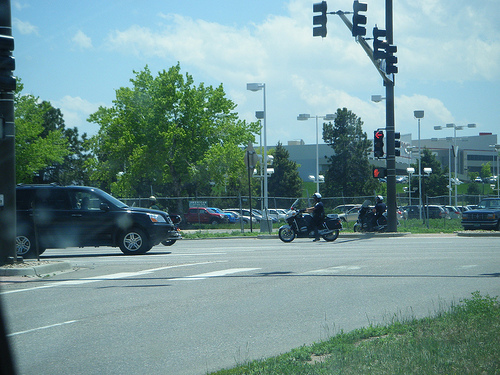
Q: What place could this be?
A: It is a road.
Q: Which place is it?
A: It is a road.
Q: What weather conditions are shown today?
A: It is clear.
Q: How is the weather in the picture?
A: It is clear.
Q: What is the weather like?
A: It is clear.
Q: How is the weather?
A: It is clear.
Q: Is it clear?
A: Yes, it is clear.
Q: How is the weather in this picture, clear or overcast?
A: It is clear.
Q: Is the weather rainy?
A: No, it is clear.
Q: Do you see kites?
A: No, there are no kites.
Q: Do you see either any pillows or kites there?
A: No, there are no kites or pillows.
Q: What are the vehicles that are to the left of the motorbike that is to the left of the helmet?
A: The vehicles are cars.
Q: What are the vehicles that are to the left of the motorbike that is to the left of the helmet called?
A: The vehicles are cars.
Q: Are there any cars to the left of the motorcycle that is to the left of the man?
A: Yes, there are cars to the left of the motorbike.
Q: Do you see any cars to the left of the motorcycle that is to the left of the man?
A: Yes, there are cars to the left of the motorbike.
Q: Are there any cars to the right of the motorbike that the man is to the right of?
A: No, the cars are to the left of the motorbike.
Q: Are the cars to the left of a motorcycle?
A: Yes, the cars are to the left of a motorcycle.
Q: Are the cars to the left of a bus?
A: No, the cars are to the left of a motorcycle.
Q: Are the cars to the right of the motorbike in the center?
A: No, the cars are to the left of the motorbike.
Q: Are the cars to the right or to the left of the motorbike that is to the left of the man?
A: The cars are to the left of the motorbike.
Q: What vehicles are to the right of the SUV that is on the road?
A: The vehicles are cars.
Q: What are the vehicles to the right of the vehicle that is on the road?
A: The vehicles are cars.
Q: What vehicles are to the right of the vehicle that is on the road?
A: The vehicles are cars.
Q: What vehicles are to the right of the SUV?
A: The vehicles are cars.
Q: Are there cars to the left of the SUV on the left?
A: No, the cars are to the right of the SUV.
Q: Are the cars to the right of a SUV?
A: Yes, the cars are to the right of a SUV.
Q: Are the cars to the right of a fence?
A: No, the cars are to the right of a SUV.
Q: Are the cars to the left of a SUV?
A: No, the cars are to the right of a SUV.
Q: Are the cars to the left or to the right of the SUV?
A: The cars are to the right of the SUV.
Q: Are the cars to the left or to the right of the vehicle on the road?
A: The cars are to the right of the SUV.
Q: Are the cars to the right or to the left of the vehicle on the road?
A: The cars are to the right of the SUV.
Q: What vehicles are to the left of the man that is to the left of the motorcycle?
A: The vehicles are cars.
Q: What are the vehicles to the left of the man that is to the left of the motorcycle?
A: The vehicles are cars.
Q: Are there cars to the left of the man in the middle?
A: Yes, there are cars to the left of the man.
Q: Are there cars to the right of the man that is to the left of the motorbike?
A: No, the cars are to the left of the man.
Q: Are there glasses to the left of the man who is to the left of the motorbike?
A: No, there are cars to the left of the man.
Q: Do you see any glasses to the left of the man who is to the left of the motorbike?
A: No, there are cars to the left of the man.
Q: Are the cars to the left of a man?
A: Yes, the cars are to the left of a man.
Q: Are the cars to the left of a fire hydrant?
A: No, the cars are to the left of a man.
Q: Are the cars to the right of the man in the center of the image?
A: No, the cars are to the left of the man.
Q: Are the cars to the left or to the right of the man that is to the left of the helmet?
A: The cars are to the left of the man.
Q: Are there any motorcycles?
A: Yes, there is a motorcycle.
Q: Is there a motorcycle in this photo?
A: Yes, there is a motorcycle.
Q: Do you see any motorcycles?
A: Yes, there is a motorcycle.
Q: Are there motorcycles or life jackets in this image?
A: Yes, there is a motorcycle.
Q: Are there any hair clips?
A: No, there are no hair clips.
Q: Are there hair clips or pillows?
A: No, there are no hair clips or pillows.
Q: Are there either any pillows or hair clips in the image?
A: No, there are no hair clips or pillows.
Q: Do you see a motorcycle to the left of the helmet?
A: Yes, there is a motorcycle to the left of the helmet.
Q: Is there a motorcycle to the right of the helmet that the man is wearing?
A: No, the motorcycle is to the left of the helmet.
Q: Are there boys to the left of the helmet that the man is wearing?
A: No, there is a motorcycle to the left of the helmet.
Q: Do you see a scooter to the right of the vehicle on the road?
A: No, there is a motorcycle to the right of the SUV.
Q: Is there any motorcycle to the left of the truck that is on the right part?
A: Yes, there is a motorcycle to the left of the truck.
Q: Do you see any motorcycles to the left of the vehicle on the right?
A: Yes, there is a motorcycle to the left of the truck.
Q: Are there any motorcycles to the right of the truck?
A: No, the motorcycle is to the left of the truck.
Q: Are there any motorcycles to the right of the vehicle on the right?
A: No, the motorcycle is to the left of the truck.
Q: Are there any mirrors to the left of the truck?
A: No, there is a motorcycle to the left of the truck.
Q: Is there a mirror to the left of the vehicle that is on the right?
A: No, there is a motorcycle to the left of the truck.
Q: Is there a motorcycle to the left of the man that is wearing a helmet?
A: Yes, there is a motorcycle to the left of the man.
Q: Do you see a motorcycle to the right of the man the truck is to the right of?
A: No, the motorcycle is to the left of the man.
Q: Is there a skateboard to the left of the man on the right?
A: No, there is a motorcycle to the left of the man.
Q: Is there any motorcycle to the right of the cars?
A: Yes, there is a motorcycle to the right of the cars.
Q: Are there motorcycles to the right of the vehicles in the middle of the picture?
A: Yes, there is a motorcycle to the right of the cars.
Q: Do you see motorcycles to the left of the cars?
A: No, the motorcycle is to the right of the cars.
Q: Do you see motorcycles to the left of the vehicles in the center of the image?
A: No, the motorcycle is to the right of the cars.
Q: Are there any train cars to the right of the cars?
A: No, there is a motorcycle to the right of the cars.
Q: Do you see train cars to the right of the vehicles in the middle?
A: No, there is a motorcycle to the right of the cars.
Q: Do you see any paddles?
A: No, there are no paddles.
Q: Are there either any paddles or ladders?
A: No, there are no paddles or ladders.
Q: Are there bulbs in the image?
A: No, there are no bulbs.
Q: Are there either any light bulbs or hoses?
A: No, there are no light bulbs or hoses.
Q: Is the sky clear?
A: Yes, the sky is clear.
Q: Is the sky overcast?
A: No, the sky is clear.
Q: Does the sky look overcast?
A: No, the sky is clear.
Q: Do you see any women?
A: No, there are no women.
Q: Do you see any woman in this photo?
A: No, there are no women.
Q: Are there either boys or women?
A: No, there are no women or boys.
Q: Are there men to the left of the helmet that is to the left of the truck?
A: Yes, there is a man to the left of the helmet.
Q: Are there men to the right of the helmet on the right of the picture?
A: No, the man is to the left of the helmet.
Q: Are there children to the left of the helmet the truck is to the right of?
A: No, there is a man to the left of the helmet.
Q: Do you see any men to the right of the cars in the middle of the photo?
A: Yes, there is a man to the right of the cars.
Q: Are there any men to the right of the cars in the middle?
A: Yes, there is a man to the right of the cars.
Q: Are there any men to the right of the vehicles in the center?
A: Yes, there is a man to the right of the cars.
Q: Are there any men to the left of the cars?
A: No, the man is to the right of the cars.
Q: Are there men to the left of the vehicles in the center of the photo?
A: No, the man is to the right of the cars.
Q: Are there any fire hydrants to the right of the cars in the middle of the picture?
A: No, there is a man to the right of the cars.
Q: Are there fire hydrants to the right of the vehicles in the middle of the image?
A: No, there is a man to the right of the cars.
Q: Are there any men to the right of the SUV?
A: Yes, there is a man to the right of the SUV.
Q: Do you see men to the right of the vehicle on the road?
A: Yes, there is a man to the right of the SUV.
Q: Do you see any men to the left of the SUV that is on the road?
A: No, the man is to the right of the SUV.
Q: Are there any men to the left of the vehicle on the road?
A: No, the man is to the right of the SUV.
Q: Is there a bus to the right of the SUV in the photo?
A: No, there is a man to the right of the SUV.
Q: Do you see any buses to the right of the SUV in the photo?
A: No, there is a man to the right of the SUV.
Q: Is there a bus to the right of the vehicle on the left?
A: No, there is a man to the right of the SUV.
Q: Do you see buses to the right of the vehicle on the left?
A: No, there is a man to the right of the SUV.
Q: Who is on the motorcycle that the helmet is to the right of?
A: The man is on the motorcycle.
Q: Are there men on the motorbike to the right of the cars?
A: Yes, there is a man on the motorcycle.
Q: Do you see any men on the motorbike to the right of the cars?
A: Yes, there is a man on the motorcycle.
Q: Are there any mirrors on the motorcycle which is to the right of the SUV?
A: No, there is a man on the motorbike.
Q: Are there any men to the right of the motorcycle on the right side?
A: No, the man is to the left of the motorbike.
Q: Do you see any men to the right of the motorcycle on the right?
A: No, the man is to the left of the motorbike.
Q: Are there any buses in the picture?
A: No, there are no buses.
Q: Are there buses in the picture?
A: No, there are no buses.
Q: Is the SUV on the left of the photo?
A: Yes, the SUV is on the left of the image.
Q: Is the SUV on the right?
A: No, the SUV is on the left of the image.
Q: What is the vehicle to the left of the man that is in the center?
A: The vehicle is a SUV.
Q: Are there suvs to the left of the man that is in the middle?
A: Yes, there is a SUV to the left of the man.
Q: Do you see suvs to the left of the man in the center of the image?
A: Yes, there is a SUV to the left of the man.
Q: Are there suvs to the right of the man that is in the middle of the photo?
A: No, the SUV is to the left of the man.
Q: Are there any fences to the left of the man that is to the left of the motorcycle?
A: No, there is a SUV to the left of the man.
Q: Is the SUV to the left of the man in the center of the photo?
A: Yes, the SUV is to the left of the man.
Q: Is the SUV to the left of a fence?
A: No, the SUV is to the left of the man.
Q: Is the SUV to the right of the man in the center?
A: No, the SUV is to the left of the man.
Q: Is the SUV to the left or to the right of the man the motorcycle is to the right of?
A: The SUV is to the left of the man.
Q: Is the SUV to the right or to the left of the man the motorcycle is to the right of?
A: The SUV is to the left of the man.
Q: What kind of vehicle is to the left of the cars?
A: The vehicle is a SUV.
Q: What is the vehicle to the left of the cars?
A: The vehicle is a SUV.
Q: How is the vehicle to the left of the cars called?
A: The vehicle is a SUV.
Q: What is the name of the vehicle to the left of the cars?
A: The vehicle is a SUV.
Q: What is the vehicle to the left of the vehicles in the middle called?
A: The vehicle is a SUV.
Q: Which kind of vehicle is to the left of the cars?
A: The vehicle is a SUV.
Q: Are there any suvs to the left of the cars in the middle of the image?
A: Yes, there is a SUV to the left of the cars.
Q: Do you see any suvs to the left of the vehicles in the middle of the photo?
A: Yes, there is a SUV to the left of the cars.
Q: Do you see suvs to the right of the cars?
A: No, the SUV is to the left of the cars.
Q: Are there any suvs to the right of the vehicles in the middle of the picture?
A: No, the SUV is to the left of the cars.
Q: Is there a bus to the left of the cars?
A: No, there is a SUV to the left of the cars.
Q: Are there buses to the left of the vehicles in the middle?
A: No, there is a SUV to the left of the cars.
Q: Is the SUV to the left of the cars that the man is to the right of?
A: Yes, the SUV is to the left of the cars.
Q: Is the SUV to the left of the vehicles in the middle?
A: Yes, the SUV is to the left of the cars.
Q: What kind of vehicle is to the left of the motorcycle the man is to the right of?
A: The vehicle is a SUV.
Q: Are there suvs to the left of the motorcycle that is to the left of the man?
A: Yes, there is a SUV to the left of the motorcycle.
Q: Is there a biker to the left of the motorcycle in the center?
A: No, there is a SUV to the left of the motorbike.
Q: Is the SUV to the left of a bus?
A: No, the SUV is to the left of the motorcycle.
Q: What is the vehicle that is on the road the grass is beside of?
A: The vehicle is a SUV.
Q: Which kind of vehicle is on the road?
A: The vehicle is a SUV.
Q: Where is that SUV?
A: The SUV is on the road.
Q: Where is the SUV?
A: The SUV is on the road.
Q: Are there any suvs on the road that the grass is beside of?
A: Yes, there is a SUV on the road.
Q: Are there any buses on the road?
A: No, there is a SUV on the road.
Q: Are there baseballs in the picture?
A: No, there are no baseballs.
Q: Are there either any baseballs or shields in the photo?
A: No, there are no baseballs or shields.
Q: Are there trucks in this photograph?
A: Yes, there is a truck.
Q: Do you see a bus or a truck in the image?
A: Yes, there is a truck.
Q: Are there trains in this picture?
A: No, there are no trains.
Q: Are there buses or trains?
A: No, there are no trains or buses.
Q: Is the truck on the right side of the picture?
A: Yes, the truck is on the right of the image.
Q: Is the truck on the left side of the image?
A: No, the truck is on the right of the image.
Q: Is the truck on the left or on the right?
A: The truck is on the right of the image.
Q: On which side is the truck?
A: The truck is on the right of the image.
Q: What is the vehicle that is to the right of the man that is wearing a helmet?
A: The vehicle is a truck.